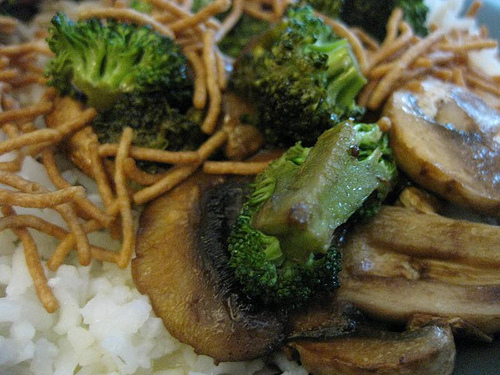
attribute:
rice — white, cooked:
[1, 1, 499, 373]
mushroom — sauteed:
[384, 85, 499, 216]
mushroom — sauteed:
[277, 309, 467, 375]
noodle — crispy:
[131, 125, 233, 208]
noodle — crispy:
[196, 156, 274, 179]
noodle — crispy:
[1, 203, 62, 317]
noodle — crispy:
[26, 103, 100, 161]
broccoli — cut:
[205, 115, 403, 320]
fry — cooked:
[3, 5, 498, 373]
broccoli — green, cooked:
[41, 10, 198, 149]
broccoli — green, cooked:
[226, 19, 368, 146]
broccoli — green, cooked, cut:
[228, 115, 396, 310]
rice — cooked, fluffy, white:
[10, 285, 147, 357]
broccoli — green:
[54, 1, 414, 301]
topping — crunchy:
[10, 101, 154, 290]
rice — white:
[13, 259, 172, 371]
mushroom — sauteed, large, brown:
[127, 163, 496, 368]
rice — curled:
[83, 301, 130, 346]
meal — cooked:
[15, 10, 472, 320]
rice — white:
[23, 280, 134, 351]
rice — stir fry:
[54, 255, 139, 358]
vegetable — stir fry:
[66, 24, 448, 314]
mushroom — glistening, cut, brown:
[385, 73, 495, 205]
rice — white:
[7, 177, 144, 367]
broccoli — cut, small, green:
[233, 3, 368, 145]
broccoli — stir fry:
[260, 120, 414, 258]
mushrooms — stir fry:
[397, 87, 437, 149]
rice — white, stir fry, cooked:
[2, 0, 308, 373]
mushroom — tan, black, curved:
[113, 169, 493, 349]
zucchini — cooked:
[131, 79, 497, 372]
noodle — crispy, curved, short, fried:
[111, 125, 138, 272]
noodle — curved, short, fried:
[200, 34, 220, 131]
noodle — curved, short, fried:
[2, 127, 57, 149]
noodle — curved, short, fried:
[374, 27, 442, 104]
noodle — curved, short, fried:
[201, 156, 271, 178]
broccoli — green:
[45, 12, 191, 154]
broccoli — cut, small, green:
[47, 10, 197, 182]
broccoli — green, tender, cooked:
[179, 126, 333, 263]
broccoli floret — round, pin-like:
[221, 121, 389, 303]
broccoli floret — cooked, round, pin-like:
[232, 3, 372, 139]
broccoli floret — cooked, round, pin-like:
[43, 10, 205, 142]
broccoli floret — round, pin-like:
[305, 3, 432, 28]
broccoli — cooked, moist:
[222, 107, 374, 281]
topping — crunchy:
[0, 1, 499, 313]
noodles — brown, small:
[1, 0, 499, 312]